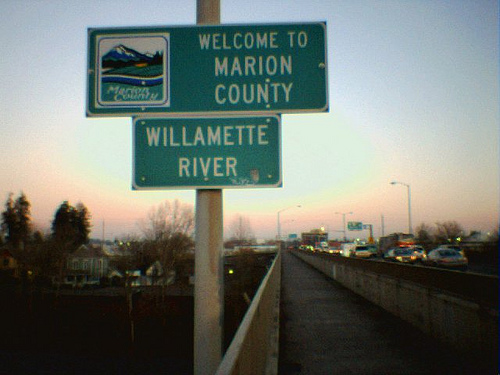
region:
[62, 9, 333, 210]
THE SIGNS ARE GREEN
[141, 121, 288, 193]
THE SIGN SAYS WILLAMETTE RIVER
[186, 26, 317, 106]
THE SIGN SAYS WELCOME TO MARION COUNTY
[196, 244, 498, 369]
THE BRIDGE IS LONG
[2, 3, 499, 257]
THE SKY IS HAZY LIKE IT IS DAWN OR MAYBE DUSK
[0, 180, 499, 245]
THE HORIZON IS PINK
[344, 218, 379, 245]
THE SIGN IS SUSPENDED ABOVE THE TRAFFIC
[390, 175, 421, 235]
THE STREET LIGHT IS TALL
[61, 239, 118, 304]
THE HOUSE IS ON THE RIVER BANK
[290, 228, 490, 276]
MANY CARS ARE ON THE BRIDGE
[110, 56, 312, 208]
This is a sign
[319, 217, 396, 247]
This is a road sign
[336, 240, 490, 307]
These are cars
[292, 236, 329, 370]
This is a deck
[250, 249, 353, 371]
This is a picture of a sidewalk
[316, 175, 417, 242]
These are streetlights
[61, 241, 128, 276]
This is a building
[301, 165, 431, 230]
The sun is rising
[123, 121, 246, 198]
This says "willamette river"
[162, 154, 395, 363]
The picture is in marion county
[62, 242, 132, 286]
a house in the left background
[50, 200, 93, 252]
a group of large pine trees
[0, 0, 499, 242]
a large patch of sky in the background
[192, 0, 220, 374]
a metal signpost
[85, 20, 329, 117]
top green sign on the signpost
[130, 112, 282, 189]
bottom green sign on the signpost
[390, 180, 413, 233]
a streetlight in the background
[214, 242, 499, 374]
a traffic bridge over water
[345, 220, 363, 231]
a green highway sign in the background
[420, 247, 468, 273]
a car on the bridge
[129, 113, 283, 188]
sign for willamette river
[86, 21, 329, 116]
sign for marion county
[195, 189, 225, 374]
section of a metal post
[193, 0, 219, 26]
section of a metal post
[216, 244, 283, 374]
a railing along a walkway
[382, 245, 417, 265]
back of a black car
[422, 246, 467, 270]
back of a small sedan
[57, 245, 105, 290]
a home in the distance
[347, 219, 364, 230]
sign in the distance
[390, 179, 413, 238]
light post along the highway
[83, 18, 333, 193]
green road signs on post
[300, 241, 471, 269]
traffic driving on road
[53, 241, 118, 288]
grey house on side of road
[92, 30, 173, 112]
photo on road sign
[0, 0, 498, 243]
blue and red sky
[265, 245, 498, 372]
a sidewalk beside the road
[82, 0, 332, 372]
road signs on side of road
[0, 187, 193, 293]
trees surrounding house on side of road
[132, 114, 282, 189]
sign with name of river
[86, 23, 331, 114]
sign welcoming people to new county